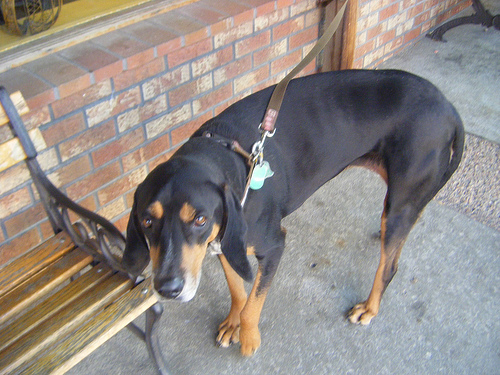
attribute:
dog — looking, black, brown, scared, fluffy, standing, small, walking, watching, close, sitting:
[119, 93, 466, 311]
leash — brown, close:
[245, 115, 285, 178]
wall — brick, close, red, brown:
[144, 32, 218, 83]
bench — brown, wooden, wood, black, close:
[5, 193, 113, 335]